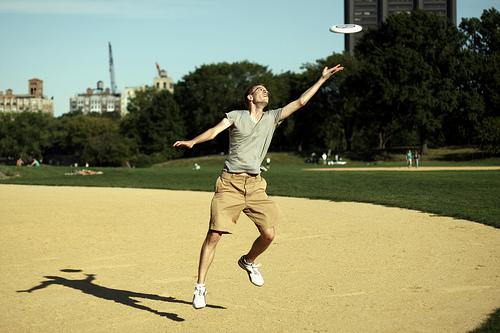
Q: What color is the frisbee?
A: White.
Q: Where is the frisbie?
A: In the air.